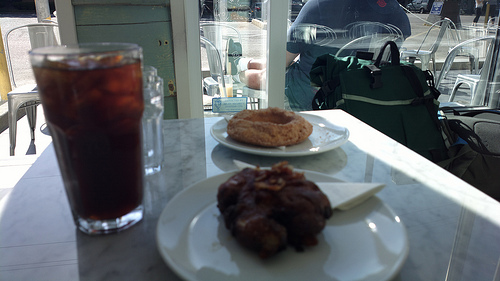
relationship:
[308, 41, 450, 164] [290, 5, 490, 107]
bag leaning against glass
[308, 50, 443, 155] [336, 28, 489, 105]
bag sitting on chair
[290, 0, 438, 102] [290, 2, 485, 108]
person sitting outside window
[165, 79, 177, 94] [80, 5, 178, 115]
hole in paint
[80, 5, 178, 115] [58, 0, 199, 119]
paint on wall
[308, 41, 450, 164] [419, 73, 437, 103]
bag with strap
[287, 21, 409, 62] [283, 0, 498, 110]
reflection on glass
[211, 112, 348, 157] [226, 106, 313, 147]
plate with donut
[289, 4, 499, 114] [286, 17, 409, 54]
window with glare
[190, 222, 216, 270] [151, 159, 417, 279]
light on plate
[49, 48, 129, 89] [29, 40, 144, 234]
ice in glass